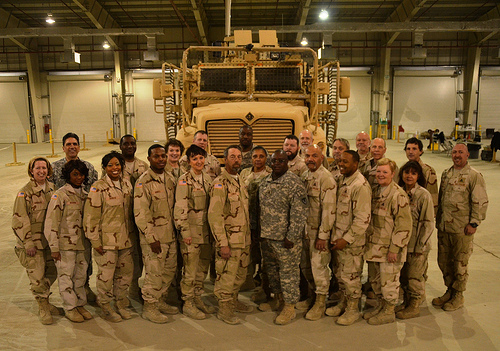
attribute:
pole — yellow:
[11, 143, 20, 165]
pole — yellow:
[46, 131, 56, 156]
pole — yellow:
[80, 135, 86, 151]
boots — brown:
[365, 299, 397, 323]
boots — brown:
[297, 287, 325, 316]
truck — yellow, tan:
[153, 22, 356, 163]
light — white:
[320, 12, 343, 32]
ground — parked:
[421, 180, 436, 207]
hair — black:
[187, 143, 205, 160]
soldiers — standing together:
[15, 97, 486, 342]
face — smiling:
[32, 157, 49, 182]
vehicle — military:
[150, 31, 349, 149]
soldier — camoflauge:
[247, 149, 318, 319]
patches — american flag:
[15, 190, 28, 199]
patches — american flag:
[50, 192, 60, 197]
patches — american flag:
[87, 183, 97, 193]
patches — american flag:
[130, 180, 146, 190]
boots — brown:
[254, 291, 302, 321]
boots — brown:
[212, 291, 260, 323]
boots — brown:
[178, 288, 216, 319]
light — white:
[296, 34, 310, 49]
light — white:
[99, 36, 111, 50]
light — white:
[42, 12, 57, 26]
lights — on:
[99, 40, 110, 50]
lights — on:
[44, 15, 55, 25]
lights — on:
[296, 37, 310, 47]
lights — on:
[314, 6, 330, 25]